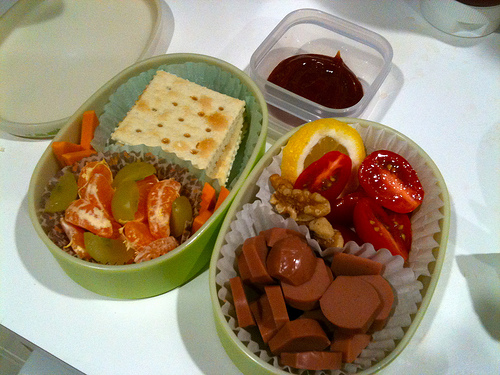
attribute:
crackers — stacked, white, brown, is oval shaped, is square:
[126, 69, 246, 183]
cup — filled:
[206, 118, 453, 361]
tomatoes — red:
[304, 153, 428, 248]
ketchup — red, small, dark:
[276, 39, 354, 119]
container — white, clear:
[242, 10, 412, 116]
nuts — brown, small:
[262, 172, 330, 240]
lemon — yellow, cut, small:
[287, 117, 355, 182]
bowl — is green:
[30, 51, 270, 306]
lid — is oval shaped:
[1, 1, 173, 137]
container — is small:
[246, 10, 394, 128]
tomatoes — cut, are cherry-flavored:
[292, 150, 423, 263]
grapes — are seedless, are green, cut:
[43, 156, 193, 266]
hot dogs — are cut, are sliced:
[222, 223, 399, 373]